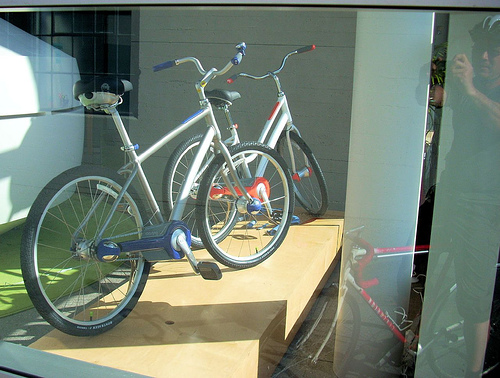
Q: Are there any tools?
A: No, there are no tools.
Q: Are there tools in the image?
A: No, there are no tools.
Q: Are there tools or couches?
A: No, there are no tools or couches.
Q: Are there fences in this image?
A: No, there are no fences.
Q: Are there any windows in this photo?
A: Yes, there is a window.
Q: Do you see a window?
A: Yes, there is a window.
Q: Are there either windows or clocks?
A: Yes, there is a window.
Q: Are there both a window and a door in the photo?
A: No, there is a window but no doors.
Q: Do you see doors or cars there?
A: No, there are no cars or doors.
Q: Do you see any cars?
A: No, there are no cars.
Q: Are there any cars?
A: No, there are no cars.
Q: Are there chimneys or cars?
A: No, there are no cars or chimneys.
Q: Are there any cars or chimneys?
A: No, there are no cars or chimneys.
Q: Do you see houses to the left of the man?
A: Yes, there is a house to the left of the man.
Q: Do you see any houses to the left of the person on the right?
A: Yes, there is a house to the left of the man.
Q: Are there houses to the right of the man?
A: No, the house is to the left of the man.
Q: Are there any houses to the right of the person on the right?
A: No, the house is to the left of the man.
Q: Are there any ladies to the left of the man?
A: No, there is a house to the left of the man.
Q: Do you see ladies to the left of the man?
A: No, there is a house to the left of the man.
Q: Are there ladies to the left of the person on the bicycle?
A: No, there is a house to the left of the man.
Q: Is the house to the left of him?
A: Yes, the house is to the left of the man.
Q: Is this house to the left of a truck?
A: No, the house is to the left of the man.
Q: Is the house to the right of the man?
A: No, the house is to the left of the man.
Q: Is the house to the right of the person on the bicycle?
A: No, the house is to the left of the man.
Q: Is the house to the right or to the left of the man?
A: The house is to the left of the man.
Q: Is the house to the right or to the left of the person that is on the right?
A: The house is to the left of the man.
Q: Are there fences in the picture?
A: No, there are no fences.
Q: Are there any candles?
A: No, there are no candles.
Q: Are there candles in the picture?
A: No, there are no candles.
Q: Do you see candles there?
A: No, there are no candles.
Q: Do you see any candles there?
A: No, there are no candles.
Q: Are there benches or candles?
A: No, there are no candles or benches.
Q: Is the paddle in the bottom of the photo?
A: Yes, the paddle is in the bottom of the image.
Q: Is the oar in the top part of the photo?
A: No, the oar is in the bottom of the image.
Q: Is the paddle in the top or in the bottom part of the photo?
A: The paddle is in the bottom of the image.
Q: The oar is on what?
A: The oar is on the bicycle.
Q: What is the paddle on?
A: The oar is on the bicycle.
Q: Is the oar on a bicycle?
A: Yes, the oar is on a bicycle.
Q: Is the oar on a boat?
A: No, the oar is on a bicycle.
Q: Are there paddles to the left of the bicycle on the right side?
A: Yes, there is a paddle to the left of the bicycle.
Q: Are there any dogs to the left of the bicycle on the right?
A: No, there is a paddle to the left of the bicycle.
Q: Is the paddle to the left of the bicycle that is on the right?
A: Yes, the paddle is to the left of the bicycle.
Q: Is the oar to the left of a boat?
A: No, the oar is to the left of the bicycle.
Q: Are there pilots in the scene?
A: No, there are no pilots.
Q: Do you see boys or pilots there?
A: No, there are no pilots or boys.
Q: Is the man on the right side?
A: Yes, the man is on the right of the image.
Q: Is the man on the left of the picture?
A: No, the man is on the right of the image.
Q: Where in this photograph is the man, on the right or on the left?
A: The man is on the right of the image.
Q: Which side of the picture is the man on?
A: The man is on the right of the image.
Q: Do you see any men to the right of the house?
A: Yes, there is a man to the right of the house.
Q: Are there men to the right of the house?
A: Yes, there is a man to the right of the house.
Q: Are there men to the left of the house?
A: No, the man is to the right of the house.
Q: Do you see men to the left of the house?
A: No, the man is to the right of the house.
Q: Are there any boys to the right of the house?
A: No, there is a man to the right of the house.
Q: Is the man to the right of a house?
A: Yes, the man is to the right of a house.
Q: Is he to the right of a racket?
A: No, the man is to the right of a house.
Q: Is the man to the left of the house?
A: No, the man is to the right of the house.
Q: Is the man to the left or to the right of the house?
A: The man is to the right of the house.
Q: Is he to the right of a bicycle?
A: Yes, the man is to the right of a bicycle.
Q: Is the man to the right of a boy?
A: No, the man is to the right of a bicycle.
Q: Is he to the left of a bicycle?
A: No, the man is to the right of a bicycle.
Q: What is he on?
A: The man is on the bicycle.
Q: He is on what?
A: The man is on the bicycle.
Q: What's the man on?
A: The man is on the bicycle.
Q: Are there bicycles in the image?
A: Yes, there is a bicycle.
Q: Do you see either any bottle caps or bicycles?
A: Yes, there is a bicycle.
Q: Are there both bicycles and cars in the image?
A: No, there is a bicycle but no cars.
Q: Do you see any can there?
A: No, there are no cans.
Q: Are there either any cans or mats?
A: No, there are no cans or mats.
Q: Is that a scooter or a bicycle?
A: That is a bicycle.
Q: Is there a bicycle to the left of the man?
A: Yes, there is a bicycle to the left of the man.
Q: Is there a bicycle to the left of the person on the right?
A: Yes, there is a bicycle to the left of the man.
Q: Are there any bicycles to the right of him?
A: No, the bicycle is to the left of the man.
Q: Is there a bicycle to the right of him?
A: No, the bicycle is to the left of the man.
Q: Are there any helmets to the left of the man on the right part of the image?
A: No, there is a bicycle to the left of the man.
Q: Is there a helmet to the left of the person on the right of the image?
A: No, there is a bicycle to the left of the man.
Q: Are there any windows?
A: Yes, there is a window.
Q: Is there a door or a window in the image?
A: Yes, there is a window.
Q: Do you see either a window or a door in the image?
A: Yes, there is a window.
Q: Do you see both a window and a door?
A: No, there is a window but no doors.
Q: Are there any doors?
A: No, there are no doors.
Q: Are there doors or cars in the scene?
A: No, there are no doors or cars.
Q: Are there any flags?
A: No, there are no flags.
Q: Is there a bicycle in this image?
A: Yes, there is a bicycle.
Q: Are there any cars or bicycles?
A: Yes, there is a bicycle.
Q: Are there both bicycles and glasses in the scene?
A: No, there is a bicycle but no glasses.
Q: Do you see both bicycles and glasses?
A: No, there is a bicycle but no glasses.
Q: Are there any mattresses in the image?
A: No, there are no mattresses.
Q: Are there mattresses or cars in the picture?
A: No, there are no mattresses or cars.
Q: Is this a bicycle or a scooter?
A: This is a bicycle.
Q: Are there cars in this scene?
A: No, there are no cars.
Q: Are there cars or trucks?
A: No, there are no cars or trucks.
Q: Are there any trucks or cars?
A: No, there are no cars or trucks.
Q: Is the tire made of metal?
A: No, the tire is made of rubber.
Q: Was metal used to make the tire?
A: No, the tire is made of rubber.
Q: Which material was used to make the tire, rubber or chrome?
A: The tire is made of rubber.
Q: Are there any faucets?
A: No, there are no faucets.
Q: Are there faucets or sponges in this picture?
A: No, there are no faucets or sponges.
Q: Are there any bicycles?
A: Yes, there is a bicycle.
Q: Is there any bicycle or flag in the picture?
A: Yes, there is a bicycle.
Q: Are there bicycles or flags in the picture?
A: Yes, there is a bicycle.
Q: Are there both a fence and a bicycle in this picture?
A: No, there is a bicycle but no fences.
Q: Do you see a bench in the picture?
A: No, there are no benches.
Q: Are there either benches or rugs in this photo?
A: No, there are no benches or rugs.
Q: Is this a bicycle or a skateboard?
A: This is a bicycle.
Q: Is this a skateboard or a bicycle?
A: This is a bicycle.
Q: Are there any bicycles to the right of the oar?
A: Yes, there is a bicycle to the right of the oar.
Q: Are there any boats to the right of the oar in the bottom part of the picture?
A: No, there is a bicycle to the right of the paddle.